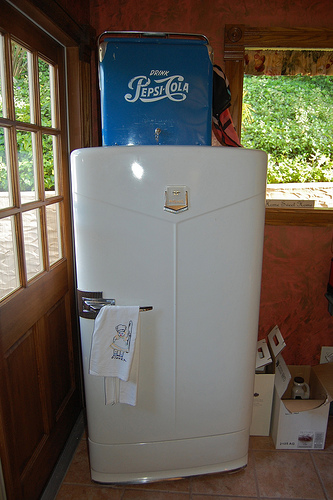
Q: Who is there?
A: No one.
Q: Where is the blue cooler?
A: On top.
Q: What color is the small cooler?
A: Blue.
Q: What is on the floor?
A: Boxes.